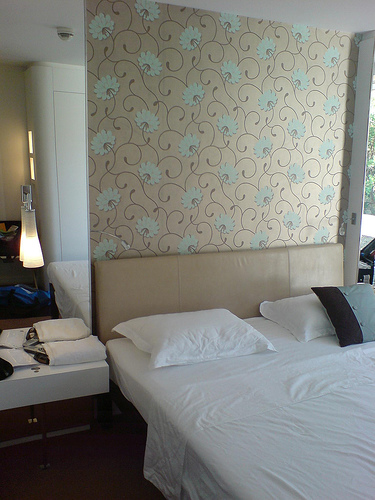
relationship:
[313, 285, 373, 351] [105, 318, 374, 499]
accent pillow on bed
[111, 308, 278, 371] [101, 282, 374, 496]
pillow on bed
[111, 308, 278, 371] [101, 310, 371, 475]
pillow on bed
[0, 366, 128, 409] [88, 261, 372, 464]
table near bed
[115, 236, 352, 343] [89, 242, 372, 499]
head on bed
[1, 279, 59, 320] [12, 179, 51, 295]
bag under light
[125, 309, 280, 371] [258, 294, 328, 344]
pillow on pillow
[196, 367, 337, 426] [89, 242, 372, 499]
sheets on bed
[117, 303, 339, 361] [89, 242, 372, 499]
pillows on bed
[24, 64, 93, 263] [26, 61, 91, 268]
reflection on cabinet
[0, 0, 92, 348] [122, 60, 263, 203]
large mirror on wall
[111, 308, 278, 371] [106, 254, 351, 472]
pillow on bed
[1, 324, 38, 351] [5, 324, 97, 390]
paper on counter